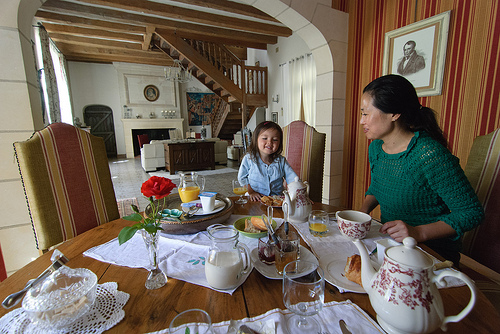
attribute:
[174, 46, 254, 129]
staircase — wooden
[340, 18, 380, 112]
wall — striped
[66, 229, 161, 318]
table — wooden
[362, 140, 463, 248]
blouse — green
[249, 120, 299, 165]
kid — smiling